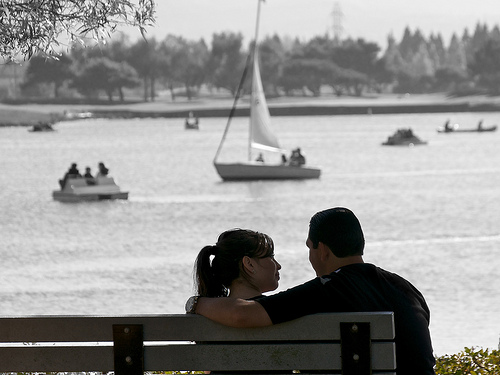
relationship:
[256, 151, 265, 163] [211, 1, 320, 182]
person on sailboat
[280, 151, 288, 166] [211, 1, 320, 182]
person on sailboat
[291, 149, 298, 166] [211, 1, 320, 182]
person on sailboat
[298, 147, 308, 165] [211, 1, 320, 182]
person on sailboat